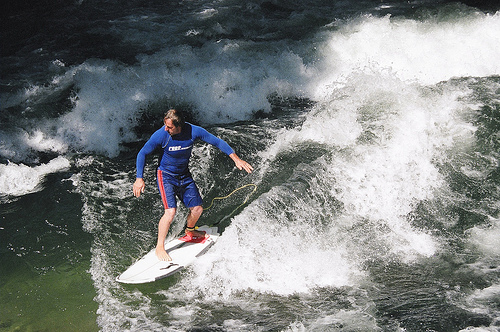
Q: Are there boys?
A: No, there are no boys.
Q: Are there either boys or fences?
A: No, there are no boys or fences.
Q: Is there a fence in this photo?
A: No, there are no fences.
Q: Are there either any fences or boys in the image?
A: No, there are no fences or boys.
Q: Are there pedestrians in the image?
A: No, there are no pedestrians.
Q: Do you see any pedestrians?
A: No, there are no pedestrians.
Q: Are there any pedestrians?
A: No, there are no pedestrians.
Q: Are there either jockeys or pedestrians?
A: No, there are no pedestrians or jockeys.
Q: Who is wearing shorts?
A: The man is wearing shorts.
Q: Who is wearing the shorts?
A: The man is wearing shorts.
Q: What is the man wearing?
A: The man is wearing shorts.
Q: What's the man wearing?
A: The man is wearing shorts.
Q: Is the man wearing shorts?
A: Yes, the man is wearing shorts.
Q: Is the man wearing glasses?
A: No, the man is wearing shorts.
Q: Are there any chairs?
A: No, there are no chairs.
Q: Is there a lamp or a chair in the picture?
A: No, there are no chairs or lamps.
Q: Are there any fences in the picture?
A: No, there are no fences.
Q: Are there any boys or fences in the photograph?
A: No, there are no fences or boys.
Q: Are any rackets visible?
A: No, there are no rackets.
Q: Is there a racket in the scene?
A: No, there are no rackets.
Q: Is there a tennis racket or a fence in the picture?
A: No, there are no rackets or fences.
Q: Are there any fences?
A: No, there are no fences.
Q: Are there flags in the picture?
A: No, there are no flags.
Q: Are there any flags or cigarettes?
A: No, there are no flags or cigarettes.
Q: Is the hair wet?
A: Yes, the hair is wet.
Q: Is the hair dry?
A: No, the hair is wet.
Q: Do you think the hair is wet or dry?
A: The hair is wet.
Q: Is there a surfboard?
A: Yes, there is a surfboard.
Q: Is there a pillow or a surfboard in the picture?
A: Yes, there is a surfboard.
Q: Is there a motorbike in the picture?
A: No, there are no motorcycles.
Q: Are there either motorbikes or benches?
A: No, there are no motorbikes or benches.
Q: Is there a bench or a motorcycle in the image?
A: No, there are no motorcycles or benches.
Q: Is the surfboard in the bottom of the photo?
A: Yes, the surfboard is in the bottom of the image.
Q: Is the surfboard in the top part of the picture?
A: No, the surfboard is in the bottom of the image.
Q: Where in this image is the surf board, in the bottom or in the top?
A: The surf board is in the bottom of the image.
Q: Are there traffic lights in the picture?
A: No, there are no traffic lights.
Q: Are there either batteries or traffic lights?
A: No, there are no traffic lights or batteries.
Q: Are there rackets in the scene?
A: No, there are no rackets.